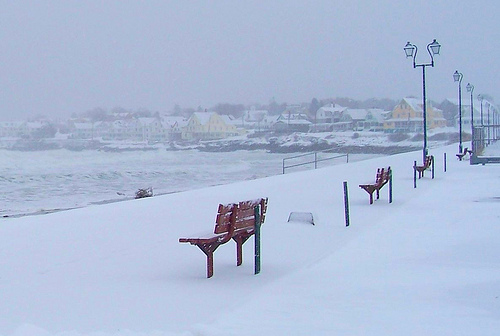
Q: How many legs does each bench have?
A: Two.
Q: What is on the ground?
A: Snow.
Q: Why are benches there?
A: For sitting.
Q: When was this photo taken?
A: Winter.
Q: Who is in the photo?
A: Noone.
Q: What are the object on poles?
A: Street lamps.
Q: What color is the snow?
A: White.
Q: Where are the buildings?
A: Background.